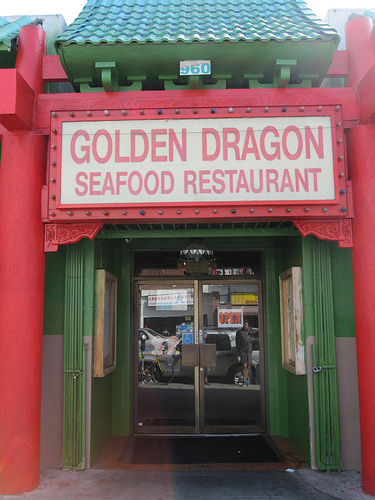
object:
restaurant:
[0, 0, 375, 500]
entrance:
[90, 236, 312, 471]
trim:
[134, 251, 261, 426]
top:
[52, 0, 341, 46]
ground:
[0, 435, 375, 499]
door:
[133, 278, 200, 435]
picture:
[103, 288, 111, 358]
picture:
[286, 275, 296, 363]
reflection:
[235, 319, 259, 388]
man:
[235, 320, 259, 388]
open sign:
[217, 308, 244, 328]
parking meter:
[141, 334, 147, 384]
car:
[138, 327, 261, 387]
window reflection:
[137, 267, 260, 390]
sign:
[47, 104, 348, 223]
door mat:
[127, 434, 282, 465]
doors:
[198, 277, 266, 437]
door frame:
[129, 248, 271, 438]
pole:
[0, 130, 48, 497]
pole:
[345, 123, 374, 500]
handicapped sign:
[182, 333, 193, 344]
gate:
[62, 237, 85, 472]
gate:
[313, 230, 342, 475]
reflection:
[137, 348, 176, 386]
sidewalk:
[0, 468, 375, 500]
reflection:
[139, 329, 261, 387]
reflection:
[138, 328, 172, 354]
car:
[138, 328, 171, 354]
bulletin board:
[93, 268, 118, 378]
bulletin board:
[278, 265, 307, 377]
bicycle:
[138, 348, 175, 385]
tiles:
[319, 28, 340, 39]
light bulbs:
[336, 105, 341, 112]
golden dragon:
[67, 124, 325, 165]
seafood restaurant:
[74, 168, 323, 197]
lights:
[52, 111, 56, 117]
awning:
[53, 0, 341, 92]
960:
[180, 60, 210, 75]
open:
[219, 311, 242, 325]